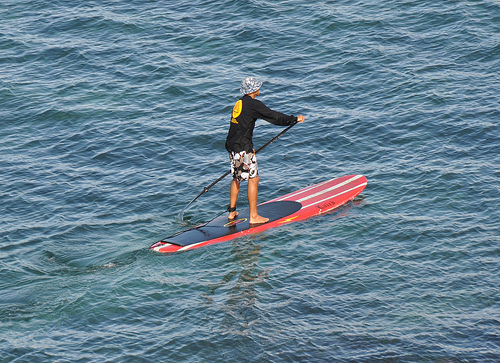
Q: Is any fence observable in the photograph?
A: No, there are no fences.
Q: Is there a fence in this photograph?
A: No, there are no fences.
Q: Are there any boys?
A: No, there are no boys.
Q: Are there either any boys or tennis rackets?
A: No, there are no boys or tennis rackets.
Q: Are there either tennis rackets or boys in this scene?
A: No, there are no boys or tennis rackets.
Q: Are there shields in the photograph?
A: No, there are no shields.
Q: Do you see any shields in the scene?
A: No, there are no shields.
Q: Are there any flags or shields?
A: No, there are no shields or flags.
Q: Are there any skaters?
A: No, there are no skaters.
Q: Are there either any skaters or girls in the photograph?
A: No, there are no skaters or girls.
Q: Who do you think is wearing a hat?
A: The man is wearing a hat.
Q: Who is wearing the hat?
A: The man is wearing a hat.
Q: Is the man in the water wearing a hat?
A: Yes, the man is wearing a hat.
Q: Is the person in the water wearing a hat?
A: Yes, the man is wearing a hat.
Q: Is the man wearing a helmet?
A: No, the man is wearing a hat.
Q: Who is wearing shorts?
A: The man is wearing shorts.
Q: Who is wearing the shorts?
A: The man is wearing shorts.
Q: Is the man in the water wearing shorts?
A: Yes, the man is wearing shorts.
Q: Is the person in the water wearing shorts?
A: Yes, the man is wearing shorts.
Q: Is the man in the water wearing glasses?
A: No, the man is wearing shorts.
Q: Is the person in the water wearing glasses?
A: No, the man is wearing shorts.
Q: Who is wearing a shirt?
A: The man is wearing a shirt.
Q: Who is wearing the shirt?
A: The man is wearing a shirt.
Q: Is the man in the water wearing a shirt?
A: Yes, the man is wearing a shirt.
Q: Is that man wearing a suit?
A: No, the man is wearing a shirt.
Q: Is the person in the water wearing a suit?
A: No, the man is wearing a shirt.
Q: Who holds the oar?
A: The man holds the oar.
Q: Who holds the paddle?
A: The man holds the oar.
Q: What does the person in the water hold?
A: The man holds the oar.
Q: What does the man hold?
A: The man holds the oar.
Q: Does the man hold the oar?
A: Yes, the man holds the oar.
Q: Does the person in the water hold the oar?
A: Yes, the man holds the oar.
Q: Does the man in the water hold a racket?
A: No, the man holds the oar.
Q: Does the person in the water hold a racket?
A: No, the man holds the oar.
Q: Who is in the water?
A: The man is in the water.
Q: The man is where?
A: The man is in the water.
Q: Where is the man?
A: The man is in the water.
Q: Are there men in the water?
A: Yes, there is a man in the water.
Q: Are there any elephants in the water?
A: No, there is a man in the water.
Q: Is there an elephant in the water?
A: No, there is a man in the water.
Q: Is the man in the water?
A: Yes, the man is in the water.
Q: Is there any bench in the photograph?
A: No, there are no benches.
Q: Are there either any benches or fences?
A: No, there are no benches or fences.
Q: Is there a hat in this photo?
A: Yes, there is a hat.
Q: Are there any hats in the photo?
A: Yes, there is a hat.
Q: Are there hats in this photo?
A: Yes, there is a hat.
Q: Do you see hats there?
A: Yes, there is a hat.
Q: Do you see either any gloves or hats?
A: Yes, there is a hat.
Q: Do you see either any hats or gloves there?
A: Yes, there is a hat.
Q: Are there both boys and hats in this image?
A: No, there is a hat but no boys.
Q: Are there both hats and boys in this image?
A: No, there is a hat but no boys.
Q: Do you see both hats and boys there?
A: No, there is a hat but no boys.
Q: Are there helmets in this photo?
A: No, there are no helmets.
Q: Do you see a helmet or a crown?
A: No, there are no helmets or crowns.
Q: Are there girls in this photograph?
A: No, there are no girls.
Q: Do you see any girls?
A: No, there are no girls.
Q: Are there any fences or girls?
A: No, there are no girls or fences.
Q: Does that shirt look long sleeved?
A: Yes, the shirt is long sleeved.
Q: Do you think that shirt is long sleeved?
A: Yes, the shirt is long sleeved.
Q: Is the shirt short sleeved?
A: No, the shirt is long sleeved.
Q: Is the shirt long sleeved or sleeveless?
A: The shirt is long sleeved.